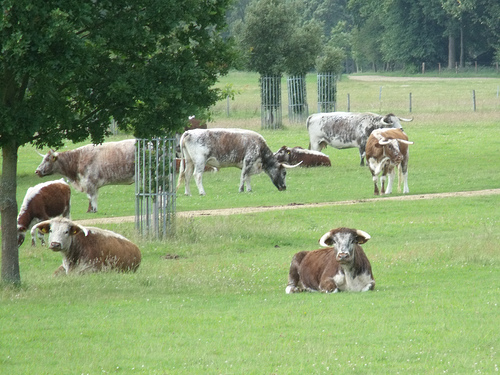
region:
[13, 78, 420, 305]
a collection of cows outside in a pasture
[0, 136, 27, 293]
a straight and narrow tree trunk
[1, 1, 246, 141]
healthy green tree foliage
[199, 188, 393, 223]
straight narrow dirt path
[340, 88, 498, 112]
a fence with metal stakes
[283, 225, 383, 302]
brown and white cow laying in the grass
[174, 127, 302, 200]
large white and browned horned cattle eating vegetation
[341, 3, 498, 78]
large back covering of tall trees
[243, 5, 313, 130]
trees with protective fencing around them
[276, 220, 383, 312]
right foreground cow laying in grass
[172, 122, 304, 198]
middle brown and white cow eating grass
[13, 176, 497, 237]
dirt path through grassy field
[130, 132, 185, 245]
metal tree support posts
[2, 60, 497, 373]
open grassy green field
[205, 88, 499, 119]
fence enclosure in field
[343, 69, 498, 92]
dirt road in distance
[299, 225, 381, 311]
Large animal laying in the grass.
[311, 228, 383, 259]
Large horns on animal's head.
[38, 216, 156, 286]
Large animal laying in grass.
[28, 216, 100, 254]
Large horns on animal's head.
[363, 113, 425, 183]
Large animal standing in grass.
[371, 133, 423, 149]
Large horns on animal's head.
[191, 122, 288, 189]
Large animal standing in grass.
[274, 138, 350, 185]
Large animal laying in grass.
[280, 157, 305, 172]
Large horns on animal's head.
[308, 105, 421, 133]
Large animal standing in grass.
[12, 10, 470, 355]
animals in an open field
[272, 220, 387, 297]
steer sitting down looking forward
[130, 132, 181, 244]
metal protection for the trunk of a tree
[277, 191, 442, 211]
narrow path running through the field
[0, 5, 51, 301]
tree growing in the field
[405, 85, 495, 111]
short fence along the property line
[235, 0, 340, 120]
three short trees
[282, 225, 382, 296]
Brown and white bull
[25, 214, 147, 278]
brown and white bull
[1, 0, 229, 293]
Tree in field with bulls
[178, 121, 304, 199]
brown and white bull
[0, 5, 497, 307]
Field full of trees and bulls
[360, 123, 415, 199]
brown and white bull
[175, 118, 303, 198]
bull eating grass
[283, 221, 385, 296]
brown and white bull sitting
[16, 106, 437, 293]
bulls relaxing and grazing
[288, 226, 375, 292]
brown cow facing forwards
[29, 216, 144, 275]
brown and white cow laying beside tree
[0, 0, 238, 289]
tree over cow laying down in grass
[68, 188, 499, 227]
dirt path next to cows